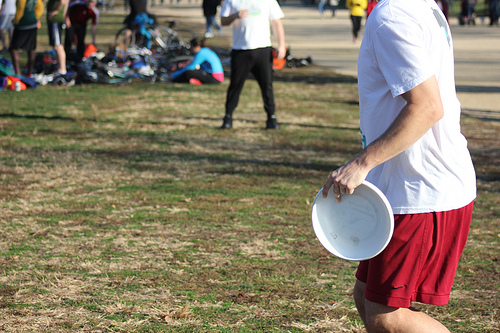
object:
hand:
[321, 162, 371, 204]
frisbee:
[309, 178, 398, 263]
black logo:
[392, 285, 407, 290]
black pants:
[224, 46, 276, 117]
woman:
[161, 38, 225, 85]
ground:
[0, 14, 500, 333]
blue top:
[171, 47, 225, 81]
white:
[55, 33, 60, 45]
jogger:
[344, 0, 368, 43]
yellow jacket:
[346, 0, 377, 17]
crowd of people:
[0, 0, 227, 88]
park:
[0, 0, 500, 333]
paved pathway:
[97, 2, 500, 110]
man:
[318, 0, 478, 333]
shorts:
[354, 198, 476, 308]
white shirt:
[356, 0, 478, 215]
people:
[61, 0, 97, 65]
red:
[393, 222, 454, 265]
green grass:
[118, 179, 226, 203]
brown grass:
[286, 138, 332, 151]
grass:
[0, 91, 181, 152]